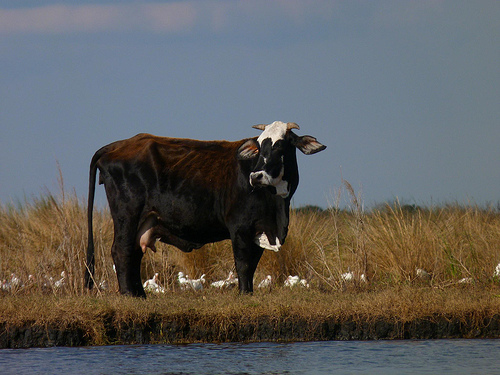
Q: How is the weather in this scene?
A: It is clear.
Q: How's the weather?
A: It is clear.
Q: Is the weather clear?
A: Yes, it is clear.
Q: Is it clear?
A: Yes, it is clear.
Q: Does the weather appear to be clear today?
A: Yes, it is clear.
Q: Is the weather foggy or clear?
A: It is clear.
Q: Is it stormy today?
A: No, it is clear.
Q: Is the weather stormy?
A: No, it is clear.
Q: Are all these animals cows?
A: No, there are both birds and cows.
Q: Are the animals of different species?
A: Yes, they are birds and cows.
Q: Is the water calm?
A: Yes, the water is calm.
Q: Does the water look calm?
A: Yes, the water is calm.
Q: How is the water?
A: The water is calm.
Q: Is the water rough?
A: No, the water is calm.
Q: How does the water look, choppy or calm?
A: The water is calm.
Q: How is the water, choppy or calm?
A: The water is calm.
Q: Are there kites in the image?
A: No, there are no kites.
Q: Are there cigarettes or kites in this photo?
A: No, there are no kites or cigarettes.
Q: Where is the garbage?
A: The garbage is in the grass.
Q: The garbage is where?
A: The garbage is in the grass.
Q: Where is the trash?
A: The garbage is in the grass.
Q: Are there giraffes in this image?
A: No, there are no giraffes.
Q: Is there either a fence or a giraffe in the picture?
A: No, there are no giraffes or fences.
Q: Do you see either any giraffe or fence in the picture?
A: No, there are no giraffes or fences.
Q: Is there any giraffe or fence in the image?
A: No, there are no giraffes or fences.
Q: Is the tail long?
A: Yes, the tail is long.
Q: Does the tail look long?
A: Yes, the tail is long.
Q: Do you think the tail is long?
A: Yes, the tail is long.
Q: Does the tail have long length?
A: Yes, the tail is long.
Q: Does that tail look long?
A: Yes, the tail is long.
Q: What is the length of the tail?
A: The tail is long.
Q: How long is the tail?
A: The tail is long.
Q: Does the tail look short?
A: No, the tail is long.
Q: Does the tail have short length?
A: No, the tail is long.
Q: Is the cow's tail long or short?
A: The tail is long.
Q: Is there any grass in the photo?
A: Yes, there is grass.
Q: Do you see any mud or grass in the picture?
A: Yes, there is grass.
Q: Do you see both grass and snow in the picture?
A: No, there is grass but no snow.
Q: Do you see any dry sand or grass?
A: Yes, there is dry grass.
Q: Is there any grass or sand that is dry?
A: Yes, the grass is dry.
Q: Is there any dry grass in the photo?
A: Yes, there is dry grass.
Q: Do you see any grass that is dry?
A: Yes, there is dry grass.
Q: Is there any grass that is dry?
A: Yes, there is grass that is dry.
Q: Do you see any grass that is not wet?
A: Yes, there is dry grass.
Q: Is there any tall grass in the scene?
A: Yes, there is tall grass.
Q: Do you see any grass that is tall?
A: Yes, there is grass that is tall.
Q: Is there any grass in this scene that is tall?
A: Yes, there is grass that is tall.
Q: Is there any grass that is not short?
A: Yes, there is tall grass.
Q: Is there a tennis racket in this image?
A: No, there are no rackets.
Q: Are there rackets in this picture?
A: No, there are no rackets.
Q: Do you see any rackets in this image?
A: No, there are no rackets.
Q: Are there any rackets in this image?
A: No, there are no rackets.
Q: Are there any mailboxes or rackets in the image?
A: No, there are no rackets or mailboxes.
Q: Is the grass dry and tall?
A: Yes, the grass is dry and tall.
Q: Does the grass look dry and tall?
A: Yes, the grass is dry and tall.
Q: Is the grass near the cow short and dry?
A: No, the grass is dry but tall.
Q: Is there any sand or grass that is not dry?
A: No, there is grass but it is dry.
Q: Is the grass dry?
A: Yes, the grass is dry.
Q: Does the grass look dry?
A: Yes, the grass is dry.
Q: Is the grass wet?
A: No, the grass is dry.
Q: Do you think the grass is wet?
A: No, the grass is dry.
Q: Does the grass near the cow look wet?
A: No, the grass is dry.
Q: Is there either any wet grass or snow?
A: No, there is grass but it is dry.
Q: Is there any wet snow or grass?
A: No, there is grass but it is dry.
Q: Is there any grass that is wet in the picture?
A: No, there is grass but it is dry.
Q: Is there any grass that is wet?
A: No, there is grass but it is dry.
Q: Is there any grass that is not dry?
A: No, there is grass but it is dry.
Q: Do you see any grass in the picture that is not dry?
A: No, there is grass but it is dry.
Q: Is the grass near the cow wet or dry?
A: The grass is dry.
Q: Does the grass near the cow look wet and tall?
A: No, the grass is tall but dry.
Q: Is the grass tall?
A: Yes, the grass is tall.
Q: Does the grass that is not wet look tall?
A: Yes, the grass is tall.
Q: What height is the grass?
A: The grass is tall.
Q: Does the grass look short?
A: No, the grass is tall.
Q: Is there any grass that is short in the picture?
A: No, there is grass but it is tall.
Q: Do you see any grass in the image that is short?
A: No, there is grass but it is tall.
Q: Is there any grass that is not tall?
A: No, there is grass but it is tall.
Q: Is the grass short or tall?
A: The grass is tall.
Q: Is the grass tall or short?
A: The grass is tall.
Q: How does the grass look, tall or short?
A: The grass is tall.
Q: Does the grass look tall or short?
A: The grass is tall.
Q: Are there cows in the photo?
A: Yes, there is a cow.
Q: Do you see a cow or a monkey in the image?
A: Yes, there is a cow.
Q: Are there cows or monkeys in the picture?
A: Yes, there is a cow.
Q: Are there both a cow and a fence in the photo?
A: No, there is a cow but no fences.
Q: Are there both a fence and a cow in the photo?
A: No, there is a cow but no fences.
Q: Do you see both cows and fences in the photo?
A: No, there is a cow but no fences.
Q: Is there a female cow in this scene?
A: Yes, there is a female cow.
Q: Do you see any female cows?
A: Yes, there is a female cow.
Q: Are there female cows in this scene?
A: Yes, there is a female cow.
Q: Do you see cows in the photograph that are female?
A: Yes, there is a cow that is female.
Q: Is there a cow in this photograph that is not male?
A: Yes, there is a female cow.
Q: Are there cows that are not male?
A: Yes, there is a female cow.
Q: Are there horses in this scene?
A: No, there are no horses.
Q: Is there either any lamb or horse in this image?
A: No, there are no horses or lambs.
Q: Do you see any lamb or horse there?
A: No, there are no horses or lambs.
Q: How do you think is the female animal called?
A: The animal is a cow.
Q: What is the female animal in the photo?
A: The animal is a cow.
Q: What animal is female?
A: The animal is a cow.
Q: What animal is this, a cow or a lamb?
A: This is a cow.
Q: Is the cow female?
A: Yes, the cow is female.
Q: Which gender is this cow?
A: The cow is female.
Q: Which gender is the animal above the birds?
A: The cow is female.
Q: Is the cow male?
A: No, the cow is female.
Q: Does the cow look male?
A: No, the cow is female.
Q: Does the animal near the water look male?
A: No, the cow is female.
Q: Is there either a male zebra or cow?
A: No, there is a cow but she is female.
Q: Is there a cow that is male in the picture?
A: No, there is a cow but she is female.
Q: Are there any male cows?
A: No, there is a cow but she is female.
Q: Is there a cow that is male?
A: No, there is a cow but she is female.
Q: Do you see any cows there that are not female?
A: No, there is a cow but she is female.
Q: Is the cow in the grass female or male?
A: The cow is female.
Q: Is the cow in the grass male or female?
A: The cow is female.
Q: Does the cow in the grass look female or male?
A: The cow is female.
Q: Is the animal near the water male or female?
A: The cow is female.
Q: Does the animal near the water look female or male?
A: The cow is female.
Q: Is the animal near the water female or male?
A: The cow is female.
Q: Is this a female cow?
A: Yes, this is a female cow.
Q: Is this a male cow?
A: No, this is a female cow.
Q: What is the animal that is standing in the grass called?
A: The animal is a cow.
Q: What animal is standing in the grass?
A: The animal is a cow.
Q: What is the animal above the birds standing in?
A: The cow is standing in the grass.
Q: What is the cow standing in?
A: The cow is standing in the grass.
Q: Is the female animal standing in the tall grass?
A: Yes, the cow is standing in the grass.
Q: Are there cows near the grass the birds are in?
A: Yes, there is a cow near the grass.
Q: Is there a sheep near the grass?
A: No, there is a cow near the grass.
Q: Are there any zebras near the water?
A: No, there is a cow near the water.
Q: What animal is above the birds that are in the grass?
A: The animal is a cow.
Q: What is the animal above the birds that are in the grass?
A: The animal is a cow.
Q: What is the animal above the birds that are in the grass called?
A: The animal is a cow.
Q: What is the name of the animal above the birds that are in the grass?
A: The animal is a cow.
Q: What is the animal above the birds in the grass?
A: The animal is a cow.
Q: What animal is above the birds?
A: The animal is a cow.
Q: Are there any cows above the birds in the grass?
A: Yes, there is a cow above the birds.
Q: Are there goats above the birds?
A: No, there is a cow above the birds.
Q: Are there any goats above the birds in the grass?
A: No, there is a cow above the birds.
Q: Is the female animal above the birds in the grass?
A: Yes, the cow is above the birds.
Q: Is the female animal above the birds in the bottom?
A: Yes, the cow is above the birds.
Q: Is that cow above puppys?
A: No, the cow is above the birds.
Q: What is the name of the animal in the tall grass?
A: The animal is a cow.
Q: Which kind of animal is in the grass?
A: The animal is a cow.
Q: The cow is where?
A: The cow is in the grass.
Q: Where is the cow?
A: The cow is in the grass.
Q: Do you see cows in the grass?
A: Yes, there is a cow in the grass.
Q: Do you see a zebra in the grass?
A: No, there is a cow in the grass.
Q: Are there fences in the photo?
A: No, there are no fences.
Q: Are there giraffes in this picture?
A: No, there are no giraffes.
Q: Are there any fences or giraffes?
A: No, there are no giraffes or fences.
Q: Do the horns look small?
A: Yes, the horns are small.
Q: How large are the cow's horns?
A: The horns are small.